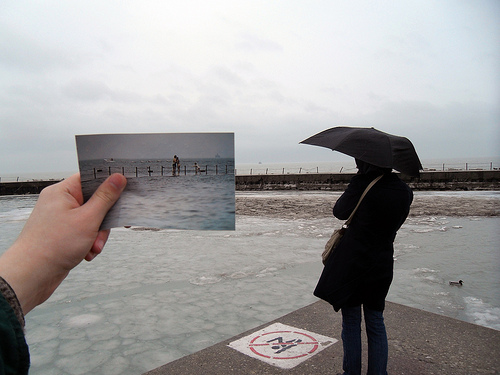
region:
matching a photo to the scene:
[23, 75, 269, 297]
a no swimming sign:
[211, 300, 303, 367]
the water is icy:
[131, 276, 241, 332]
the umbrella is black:
[285, 100, 451, 264]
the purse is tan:
[283, 97, 443, 322]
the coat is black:
[278, 95, 427, 352]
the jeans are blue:
[275, 100, 439, 372]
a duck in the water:
[437, 257, 496, 312]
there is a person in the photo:
[51, 82, 302, 269]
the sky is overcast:
[268, 75, 480, 304]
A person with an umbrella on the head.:
[300, 125, 423, 373]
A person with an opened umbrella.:
[299, 125, 427, 372]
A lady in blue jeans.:
[302, 120, 425, 372]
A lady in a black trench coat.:
[297, 120, 426, 372]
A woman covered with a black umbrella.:
[299, 123, 426, 373]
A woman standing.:
[299, 122, 425, 369]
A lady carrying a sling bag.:
[296, 115, 425, 372]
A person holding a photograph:
[1, 128, 237, 368]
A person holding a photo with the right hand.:
[0, 131, 237, 373]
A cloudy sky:
[1, 2, 486, 96]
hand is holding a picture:
[45, 110, 240, 354]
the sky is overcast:
[82, 39, 377, 109]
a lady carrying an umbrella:
[305, 107, 443, 366]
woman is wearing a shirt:
[296, 170, 429, 326]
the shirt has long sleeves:
[315, 165, 446, 244]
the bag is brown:
[293, 162, 423, 309]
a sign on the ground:
[231, 310, 315, 366]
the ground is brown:
[393, 316, 485, 369]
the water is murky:
[168, 268, 364, 331]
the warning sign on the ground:
[232, 321, 336, 367]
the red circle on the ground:
[250, 330, 319, 357]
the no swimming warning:
[249, 327, 318, 360]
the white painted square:
[228, 320, 337, 368]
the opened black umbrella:
[298, 125, 423, 170]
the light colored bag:
[321, 174, 386, 266]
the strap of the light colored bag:
[345, 172, 387, 222]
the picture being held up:
[73, 132, 233, 229]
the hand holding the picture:
[3, 172, 130, 304]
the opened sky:
[76, 15, 406, 101]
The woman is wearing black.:
[300, 109, 427, 369]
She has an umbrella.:
[289, 116, 431, 196]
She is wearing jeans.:
[300, 94, 439, 366]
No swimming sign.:
[216, 301, 326, 374]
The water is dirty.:
[129, 249, 256, 326]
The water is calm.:
[111, 242, 278, 336]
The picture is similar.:
[29, 107, 301, 266]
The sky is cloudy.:
[40, 12, 454, 108]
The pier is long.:
[34, 154, 391, 199]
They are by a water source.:
[5, 15, 494, 330]